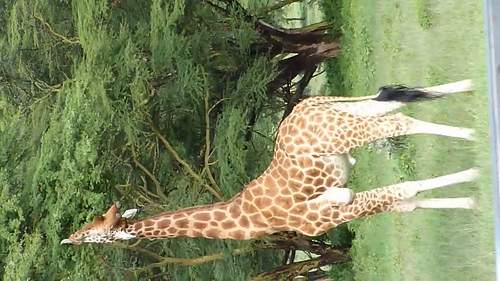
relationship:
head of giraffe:
[62, 208, 129, 249] [53, 75, 474, 250]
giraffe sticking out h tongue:
[53, 75, 474, 250] [59, 237, 72, 250]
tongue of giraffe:
[59, 237, 72, 250] [53, 75, 474, 250]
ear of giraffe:
[112, 228, 136, 240] [53, 75, 474, 250]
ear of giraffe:
[122, 203, 138, 220] [53, 75, 474, 250]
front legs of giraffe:
[364, 169, 475, 221] [53, 75, 474, 250]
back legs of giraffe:
[351, 80, 474, 141] [53, 75, 474, 250]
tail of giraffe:
[320, 79, 426, 104] [53, 75, 474, 250]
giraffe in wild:
[53, 75, 474, 250] [3, 3, 496, 280]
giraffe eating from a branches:
[53, 75, 474, 250] [0, 0, 342, 280]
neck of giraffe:
[135, 187, 251, 247] [53, 75, 474, 250]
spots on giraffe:
[148, 98, 398, 242] [53, 75, 474, 250]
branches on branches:
[37, 2, 287, 280] [0, 0, 342, 280]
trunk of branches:
[268, 15, 333, 75] [0, 0, 342, 280]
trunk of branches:
[282, 231, 342, 273] [0, 0, 342, 280]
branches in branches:
[0, 0, 342, 280] [0, 0, 342, 280]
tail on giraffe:
[320, 79, 426, 104] [53, 75, 474, 250]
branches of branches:
[37, 2, 287, 280] [0, 0, 342, 280]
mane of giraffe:
[140, 196, 225, 224] [53, 75, 474, 250]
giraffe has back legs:
[53, 75, 474, 250] [351, 80, 474, 141]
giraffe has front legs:
[53, 75, 474, 250] [364, 169, 475, 221]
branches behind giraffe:
[0, 0, 342, 280] [53, 75, 474, 250]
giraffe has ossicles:
[53, 75, 474, 250] [86, 205, 104, 227]